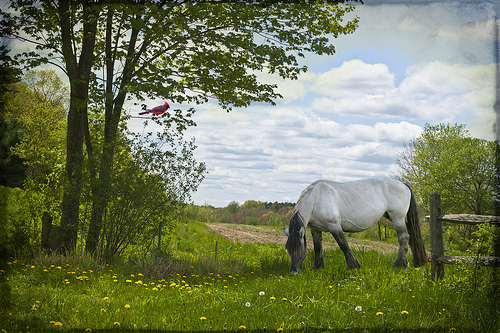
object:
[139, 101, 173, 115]
bird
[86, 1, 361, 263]
tree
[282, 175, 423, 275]
horse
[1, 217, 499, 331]
grass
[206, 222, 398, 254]
road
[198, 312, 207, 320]
flower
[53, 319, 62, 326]
flower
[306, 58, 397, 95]
cloud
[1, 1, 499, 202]
sky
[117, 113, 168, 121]
branch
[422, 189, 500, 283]
fence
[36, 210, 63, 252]
stump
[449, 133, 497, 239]
tree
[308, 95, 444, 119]
cloud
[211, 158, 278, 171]
cloud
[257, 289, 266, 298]
dandelion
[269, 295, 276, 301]
dandelion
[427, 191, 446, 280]
post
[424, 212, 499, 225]
rail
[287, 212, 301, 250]
mane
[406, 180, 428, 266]
tail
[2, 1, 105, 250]
tree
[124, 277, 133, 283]
dandelion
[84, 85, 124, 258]
trunk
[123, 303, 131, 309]
flower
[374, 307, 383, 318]
flower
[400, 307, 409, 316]
flower